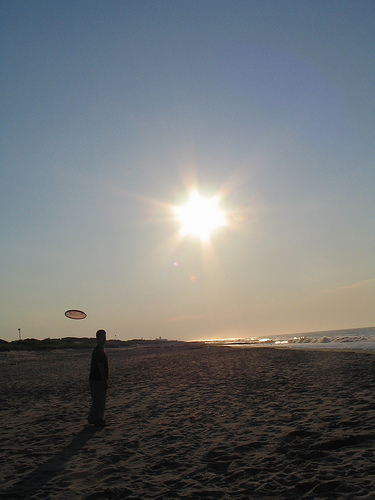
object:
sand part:
[182, 429, 206, 448]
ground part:
[40, 431, 375, 492]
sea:
[274, 322, 362, 345]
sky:
[0, 4, 375, 171]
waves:
[242, 330, 354, 349]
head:
[96, 329, 107, 345]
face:
[96, 329, 106, 346]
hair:
[96, 329, 107, 343]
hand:
[105, 381, 109, 387]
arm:
[97, 353, 106, 381]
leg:
[94, 381, 106, 418]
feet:
[87, 416, 103, 425]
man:
[85, 327, 110, 429]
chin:
[104, 339, 107, 343]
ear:
[96, 335, 99, 340]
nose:
[104, 338, 106, 341]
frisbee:
[64, 309, 88, 321]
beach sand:
[140, 385, 300, 497]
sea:
[241, 331, 359, 343]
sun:
[158, 178, 240, 250]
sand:
[217, 367, 371, 437]